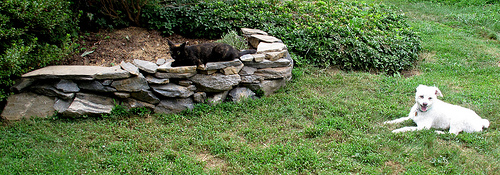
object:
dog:
[382, 84, 489, 138]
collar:
[410, 104, 427, 116]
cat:
[162, 38, 267, 68]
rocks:
[128, 59, 159, 74]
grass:
[0, 4, 498, 174]